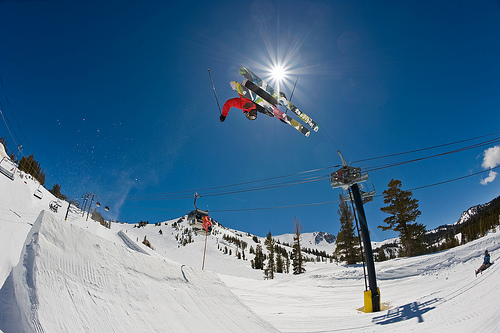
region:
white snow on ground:
[71, 245, 133, 309]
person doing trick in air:
[216, 69, 326, 150]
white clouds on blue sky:
[6, 13, 94, 77]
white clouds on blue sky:
[29, 71, 93, 126]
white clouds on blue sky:
[92, 138, 194, 185]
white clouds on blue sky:
[208, 145, 289, 207]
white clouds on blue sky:
[138, 41, 178, 82]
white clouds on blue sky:
[351, 36, 413, 88]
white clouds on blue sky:
[369, 98, 431, 162]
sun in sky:
[266, 59, 298, 91]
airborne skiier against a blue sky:
[195, 42, 332, 151]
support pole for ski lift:
[300, 142, 414, 318]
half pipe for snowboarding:
[13, 200, 283, 330]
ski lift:
[2, 179, 495, 224]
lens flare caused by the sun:
[213, 36, 344, 112]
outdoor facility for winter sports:
[4, 19, 497, 331]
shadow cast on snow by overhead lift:
[351, 287, 459, 326]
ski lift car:
[179, 187, 226, 244]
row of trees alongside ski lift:
[240, 156, 499, 295]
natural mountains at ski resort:
[19, 173, 424, 279]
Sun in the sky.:
[261, 55, 296, 83]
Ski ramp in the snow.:
[2, 196, 262, 327]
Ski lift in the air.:
[180, 187, 215, 232]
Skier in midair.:
[200, 55, 327, 145]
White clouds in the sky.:
[475, 141, 495, 182]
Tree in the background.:
[380, 170, 427, 260]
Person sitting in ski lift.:
[197, 212, 212, 232]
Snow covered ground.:
[0, 135, 499, 329]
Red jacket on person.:
[215, 83, 257, 125]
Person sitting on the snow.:
[475, 248, 493, 278]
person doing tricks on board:
[217, 63, 324, 151]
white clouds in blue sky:
[35, 13, 101, 65]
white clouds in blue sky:
[126, 56, 187, 117]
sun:
[260, 46, 297, 91]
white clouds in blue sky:
[29, 93, 122, 151]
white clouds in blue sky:
[191, 162, 267, 201]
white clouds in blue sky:
[376, 51, 440, 108]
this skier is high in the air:
[50, 52, 455, 325]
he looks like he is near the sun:
[196, 43, 337, 139]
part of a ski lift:
[311, 154, 408, 318]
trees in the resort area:
[218, 182, 433, 283]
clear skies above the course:
[60, 27, 470, 167]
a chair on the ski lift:
[177, 183, 220, 248]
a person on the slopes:
[460, 245, 496, 275]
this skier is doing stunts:
[192, 65, 337, 141]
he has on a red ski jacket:
[197, 90, 307, 146]